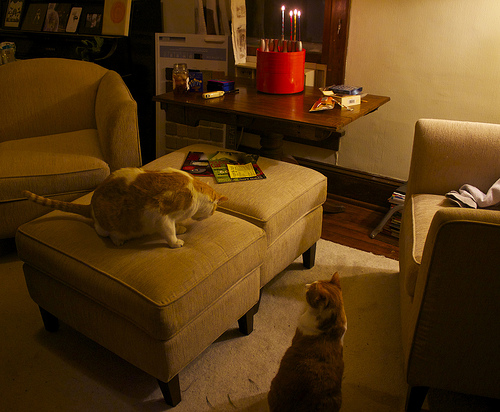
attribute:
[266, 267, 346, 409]
cat — brown, white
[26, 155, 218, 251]
cat — orange, white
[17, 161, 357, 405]
cats — male, female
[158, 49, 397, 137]
table — small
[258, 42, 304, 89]
cup — red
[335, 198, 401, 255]
floor — hardwood